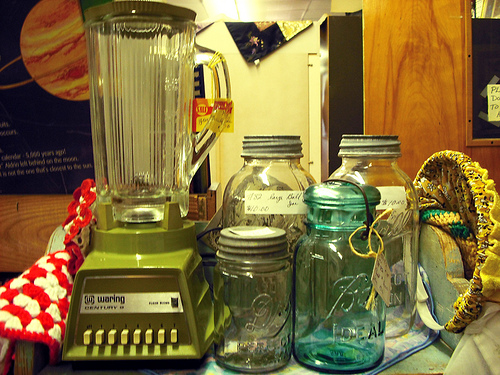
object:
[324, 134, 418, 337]
jars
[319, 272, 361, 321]
writing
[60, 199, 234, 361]
base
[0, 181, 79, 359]
clothing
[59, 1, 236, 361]
blender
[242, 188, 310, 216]
stickers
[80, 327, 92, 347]
buttons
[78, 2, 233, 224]
pitcher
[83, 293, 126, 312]
logo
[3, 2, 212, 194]
poster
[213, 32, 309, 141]
wall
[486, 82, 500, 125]
note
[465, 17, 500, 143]
window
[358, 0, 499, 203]
door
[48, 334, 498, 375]
table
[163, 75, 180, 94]
words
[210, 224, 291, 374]
glass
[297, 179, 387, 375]
glasses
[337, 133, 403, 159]
top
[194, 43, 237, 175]
handle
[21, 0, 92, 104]
planet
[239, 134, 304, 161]
latch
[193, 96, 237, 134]
tag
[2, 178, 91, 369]
mitt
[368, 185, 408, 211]
tag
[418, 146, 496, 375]
napkin holder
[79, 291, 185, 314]
label